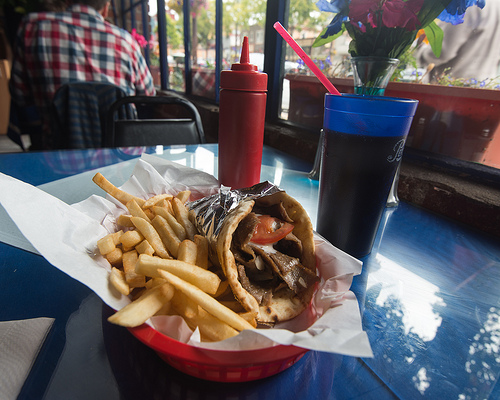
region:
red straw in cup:
[261, 5, 355, 105]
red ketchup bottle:
[204, 25, 284, 212]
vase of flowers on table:
[318, 0, 455, 240]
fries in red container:
[87, 169, 251, 359]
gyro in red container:
[165, 162, 340, 341]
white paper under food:
[0, 151, 400, 391]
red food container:
[118, 285, 338, 390]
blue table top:
[0, 132, 499, 398]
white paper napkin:
[0, 297, 65, 398]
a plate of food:
[83, 160, 343, 394]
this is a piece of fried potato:
[105, 285, 185, 325]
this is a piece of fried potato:
[97, 234, 145, 260]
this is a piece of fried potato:
[91, 168, 165, 216]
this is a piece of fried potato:
[129, 248, 220, 305]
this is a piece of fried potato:
[155, 260, 263, 331]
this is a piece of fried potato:
[165, 292, 248, 351]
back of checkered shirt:
[11, 7, 155, 126]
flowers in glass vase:
[316, 0, 481, 91]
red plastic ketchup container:
[215, 37, 270, 186]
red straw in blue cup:
[272, 21, 417, 261]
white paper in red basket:
[1, 150, 371, 384]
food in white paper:
[92, 171, 317, 331]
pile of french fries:
[90, 173, 255, 338]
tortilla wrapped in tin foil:
[189, 182, 315, 323]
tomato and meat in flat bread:
[222, 195, 312, 324]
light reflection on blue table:
[3, 140, 497, 397]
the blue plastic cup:
[316, 90, 417, 260]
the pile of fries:
[89, 171, 257, 340]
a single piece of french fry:
[158, 266, 257, 330]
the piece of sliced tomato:
[251, 210, 293, 242]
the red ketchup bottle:
[218, 35, 267, 188]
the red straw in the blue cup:
[273, 20, 418, 262]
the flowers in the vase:
[310, 0, 486, 99]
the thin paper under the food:
[0, 151, 375, 358]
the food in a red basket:
[0, 150, 373, 382]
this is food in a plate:
[69, 165, 342, 372]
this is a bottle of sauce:
[197, 13, 291, 185]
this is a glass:
[303, 68, 413, 263]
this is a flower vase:
[326, 0, 442, 98]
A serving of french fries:
[87, 171, 219, 348]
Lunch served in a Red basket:
[102, 163, 333, 383]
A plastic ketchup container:
[208, 30, 274, 192]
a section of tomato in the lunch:
[245, 211, 296, 248]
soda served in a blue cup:
[313, 84, 420, 262]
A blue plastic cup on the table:
[317, 80, 421, 271]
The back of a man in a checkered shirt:
[18, 2, 159, 117]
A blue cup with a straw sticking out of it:
[267, 16, 427, 258]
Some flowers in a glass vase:
[322, 5, 429, 80]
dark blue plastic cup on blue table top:
[314, 85, 421, 260]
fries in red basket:
[86, 169, 259, 346]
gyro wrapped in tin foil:
[179, 175, 319, 331]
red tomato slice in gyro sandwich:
[246, 208, 297, 248]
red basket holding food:
[0, 145, 377, 398]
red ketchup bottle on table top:
[210, 32, 273, 195]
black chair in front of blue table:
[96, 90, 208, 151]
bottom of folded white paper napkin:
[1, 309, 59, 399]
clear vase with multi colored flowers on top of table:
[309, 1, 491, 99]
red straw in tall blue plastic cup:
[267, 19, 345, 95]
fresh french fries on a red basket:
[77, 166, 224, 351]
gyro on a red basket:
[192, 172, 322, 322]